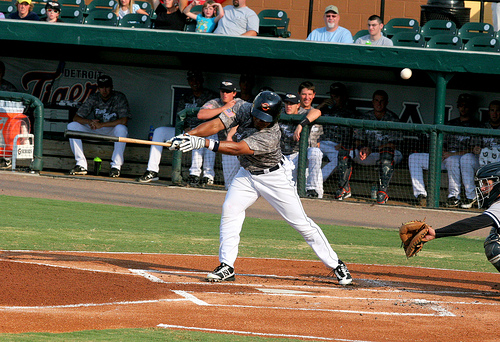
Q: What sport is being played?
A: Baseball.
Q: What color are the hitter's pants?
A: White.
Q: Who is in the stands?
A: Fans.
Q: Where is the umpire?
A: Hidden.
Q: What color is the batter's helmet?
A: Black.